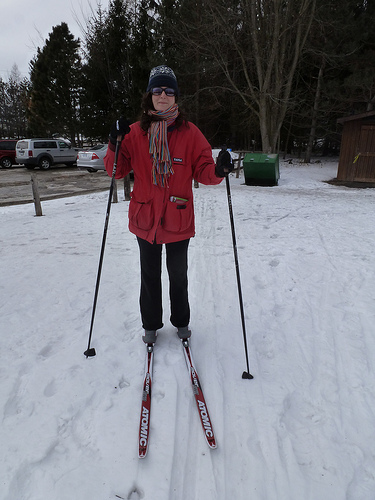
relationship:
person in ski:
[98, 56, 228, 345] [134, 332, 154, 459]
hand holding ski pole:
[213, 142, 234, 176] [220, 139, 258, 384]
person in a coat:
[98, 56, 228, 345] [100, 118, 223, 245]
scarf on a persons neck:
[147, 103, 181, 187] [142, 105, 178, 126]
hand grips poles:
[213, 142, 234, 176] [219, 166, 254, 381]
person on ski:
[98, 56, 228, 345] [180, 338, 216, 449]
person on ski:
[98, 56, 228, 345] [136, 329, 155, 457]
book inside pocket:
[168, 195, 188, 201] [161, 200, 194, 233]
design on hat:
[144, 56, 182, 91] [143, 62, 179, 96]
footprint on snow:
[43, 362, 84, 397] [9, 152, 362, 491]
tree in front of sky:
[21, 25, 85, 146] [3, 0, 148, 94]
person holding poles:
[98, 56, 228, 345] [188, 166, 279, 409]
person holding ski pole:
[98, 56, 228, 345] [81, 132, 124, 361]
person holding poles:
[98, 56, 228, 263] [219, 166, 254, 381]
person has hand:
[98, 56, 228, 263] [212, 143, 236, 178]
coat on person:
[92, 113, 228, 244] [99, 59, 236, 341]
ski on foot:
[176, 331, 221, 461] [172, 317, 197, 342]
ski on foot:
[131, 332, 159, 460] [134, 317, 161, 347]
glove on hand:
[211, 147, 234, 178] [215, 143, 235, 176]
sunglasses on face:
[150, 85, 178, 102] [147, 84, 179, 116]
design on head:
[144, 61, 182, 81] [147, 65, 183, 121]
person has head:
[98, 56, 228, 345] [147, 65, 183, 121]